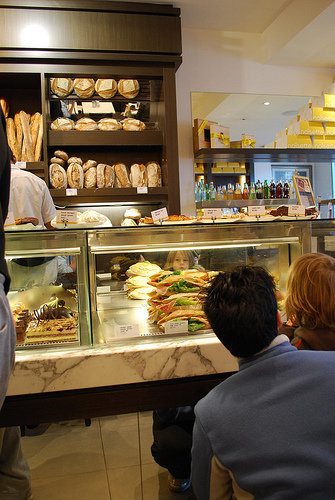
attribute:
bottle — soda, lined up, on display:
[214, 180, 226, 202]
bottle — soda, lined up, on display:
[233, 178, 245, 203]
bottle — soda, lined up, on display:
[256, 178, 264, 201]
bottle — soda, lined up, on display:
[267, 178, 279, 203]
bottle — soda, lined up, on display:
[281, 176, 291, 203]